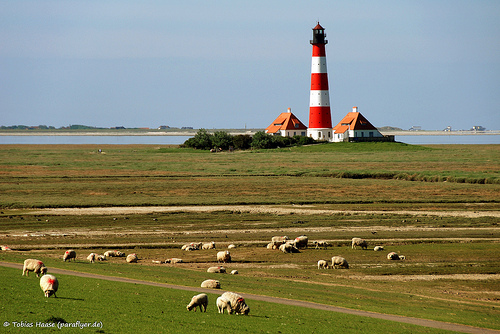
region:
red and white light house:
[307, 22, 332, 141]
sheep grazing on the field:
[25, 226, 399, 309]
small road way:
[7, 260, 481, 331]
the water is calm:
[0, 133, 497, 141]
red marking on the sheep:
[47, 276, 56, 284]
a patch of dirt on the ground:
[366, 273, 498, 278]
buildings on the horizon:
[404, 123, 486, 132]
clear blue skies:
[2, 3, 498, 123]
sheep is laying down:
[197, 278, 224, 288]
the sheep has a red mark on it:
[43, 274, 60, 293]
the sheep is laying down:
[199, 272, 222, 292]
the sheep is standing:
[20, 252, 49, 277]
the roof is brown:
[277, 117, 289, 127]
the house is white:
[350, 132, 361, 141]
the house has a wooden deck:
[347, 132, 397, 145]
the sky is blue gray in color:
[396, 82, 433, 109]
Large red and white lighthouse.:
[309, 19, 335, 149]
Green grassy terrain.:
[41, 161, 416, 213]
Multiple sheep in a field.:
[15, 238, 417, 321]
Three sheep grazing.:
[174, 289, 252, 321]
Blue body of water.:
[6, 128, 498, 145]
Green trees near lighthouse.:
[180, 125, 302, 150]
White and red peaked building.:
[331, 105, 386, 140]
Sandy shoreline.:
[5, 125, 210, 132]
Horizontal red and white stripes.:
[308, 41, 333, 142]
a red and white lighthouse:
[306, 20, 331, 142]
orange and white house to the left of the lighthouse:
[264, 107, 305, 137]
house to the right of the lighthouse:
[331, 105, 386, 140]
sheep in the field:
[0, 234, 407, 316]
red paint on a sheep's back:
[46, 275, 54, 286]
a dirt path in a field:
[0, 255, 497, 331]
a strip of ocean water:
[1, 131, 498, 149]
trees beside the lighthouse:
[182, 128, 327, 147]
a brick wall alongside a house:
[343, 134, 397, 142]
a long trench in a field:
[3, 168, 498, 191]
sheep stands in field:
[37, 269, 60, 297]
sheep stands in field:
[23, 258, 47, 278]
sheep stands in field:
[186, 290, 208, 313]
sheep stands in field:
[214, 294, 235, 314]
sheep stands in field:
[223, 292, 250, 314]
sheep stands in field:
[200, 277, 222, 289]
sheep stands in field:
[62, 250, 77, 263]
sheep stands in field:
[315, 257, 329, 268]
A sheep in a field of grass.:
[181, 294, 207, 312]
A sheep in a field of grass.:
[37, 270, 65, 297]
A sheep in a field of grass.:
[18, 257, 40, 272]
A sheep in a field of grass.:
[84, 253, 93, 260]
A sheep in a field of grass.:
[122, 251, 136, 263]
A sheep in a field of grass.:
[206, 263, 220, 273]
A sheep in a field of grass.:
[213, 250, 233, 260]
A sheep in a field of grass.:
[296, 234, 308, 246]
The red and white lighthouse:
[307, 20, 332, 141]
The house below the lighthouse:
[263, 106, 306, 135]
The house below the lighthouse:
[328, 105, 381, 143]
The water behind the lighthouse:
[1, 133, 499, 143]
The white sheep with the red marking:
[37, 272, 61, 298]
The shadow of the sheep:
[53, 293, 83, 301]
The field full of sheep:
[1, 144, 498, 332]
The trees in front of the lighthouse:
[183, 126, 326, 151]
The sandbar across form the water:
[0, 129, 497, 134]